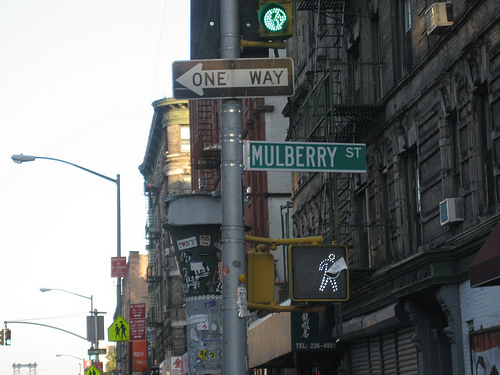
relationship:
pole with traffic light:
[210, 3, 252, 374] [257, 0, 290, 37]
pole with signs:
[210, 3, 252, 374] [242, 134, 369, 176]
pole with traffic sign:
[210, 3, 252, 374] [166, 54, 294, 96]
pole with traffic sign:
[210, 3, 252, 374] [290, 235, 350, 304]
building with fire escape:
[317, 20, 485, 285] [312, 30, 385, 257]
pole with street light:
[110, 175, 124, 256] [39, 285, 53, 292]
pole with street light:
[110, 175, 124, 256] [53, 351, 62, 358]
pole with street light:
[110, 175, 124, 256] [9, 149, 37, 164]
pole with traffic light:
[88, 295, 95, 313] [4, 326, 13, 348]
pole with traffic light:
[88, 295, 95, 313] [0, 327, 7, 344]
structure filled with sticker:
[164, 188, 223, 373] [173, 234, 198, 250]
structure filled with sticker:
[164, 188, 223, 373] [198, 233, 210, 245]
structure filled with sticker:
[164, 188, 223, 373] [185, 260, 205, 273]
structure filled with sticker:
[164, 188, 223, 373] [198, 249, 213, 259]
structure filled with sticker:
[164, 188, 223, 373] [181, 249, 193, 263]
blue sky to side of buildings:
[1, 0, 190, 90] [116, 0, 498, 373]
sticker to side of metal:
[173, 230, 198, 253] [166, 229, 221, 291]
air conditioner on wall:
[424, 192, 474, 237] [388, 57, 473, 171]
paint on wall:
[433, 287, 495, 362] [431, 268, 493, 315]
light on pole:
[11, 151, 35, 164] [35, 151, 124, 373]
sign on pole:
[240, 134, 377, 182] [219, 105, 254, 367]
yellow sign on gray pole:
[240, 5, 295, 53] [218, 0, 251, 372]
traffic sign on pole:
[290, 235, 350, 304] [210, 3, 252, 374]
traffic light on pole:
[253, 6, 305, 53] [208, 100, 255, 356]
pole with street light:
[117, 176, 121, 373] [11, 158, 117, 181]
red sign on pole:
[108, 253, 130, 283] [96, 173, 156, 373]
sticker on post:
[173, 230, 198, 253] [166, 190, 223, 372]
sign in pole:
[106, 317, 131, 341] [6, 149, 126, 371]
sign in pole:
[110, 256, 125, 276] [6, 149, 126, 371]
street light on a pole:
[9, 149, 37, 164] [6, 149, 126, 371]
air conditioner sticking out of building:
[433, 192, 471, 227] [275, 15, 497, 372]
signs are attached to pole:
[165, 49, 368, 176] [223, 110, 252, 374]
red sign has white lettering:
[108, 253, 130, 283] [111, 256, 128, 277]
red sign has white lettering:
[124, 300, 149, 342] [245, 141, 363, 168]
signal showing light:
[5, 327, 15, 349] [6, 338, 12, 343]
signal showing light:
[244, 0, 294, 46] [263, 5, 287, 30]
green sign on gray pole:
[246, 137, 368, 175] [200, 99, 279, 373]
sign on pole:
[220, 0, 247, 373] [221, 1, 245, 373]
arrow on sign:
[174, 62, 292, 97] [190, 112, 372, 192]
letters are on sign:
[250, 143, 362, 167] [240, 134, 377, 182]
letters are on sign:
[188, 69, 284, 86] [240, 134, 377, 182]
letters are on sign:
[131, 346, 148, 362] [170, 55, 295, 98]